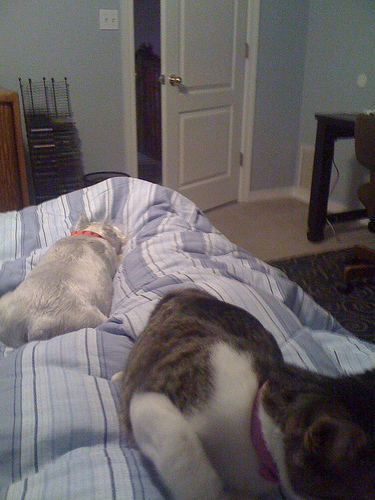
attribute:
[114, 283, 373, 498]
cat — black, white, dark grey, gray, tabby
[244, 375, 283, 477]
collar — purple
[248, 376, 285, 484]
collar — purple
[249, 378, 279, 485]
collar — purple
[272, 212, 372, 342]
rug — dark colored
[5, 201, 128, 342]
cat — light gray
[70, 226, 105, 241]
collar — orange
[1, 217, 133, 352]
dog — white, gray, black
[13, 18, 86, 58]
wall — blue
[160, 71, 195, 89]
door knob — gold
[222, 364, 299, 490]
collar — lavender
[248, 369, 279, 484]
collar — purple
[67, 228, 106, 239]
collar — red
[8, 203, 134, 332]
cat — grey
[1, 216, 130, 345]
cat — prone, white, orange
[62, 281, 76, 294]
fur — grey